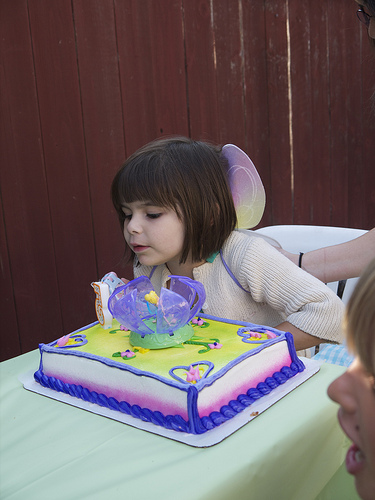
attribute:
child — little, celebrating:
[109, 133, 349, 356]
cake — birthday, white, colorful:
[31, 267, 308, 439]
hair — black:
[110, 142, 239, 265]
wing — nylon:
[106, 273, 156, 333]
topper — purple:
[106, 273, 207, 336]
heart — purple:
[167, 358, 216, 389]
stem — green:
[184, 336, 222, 357]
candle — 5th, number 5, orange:
[89, 269, 131, 329]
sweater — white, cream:
[126, 232, 346, 349]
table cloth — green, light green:
[1, 345, 353, 500]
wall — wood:
[1, 4, 375, 366]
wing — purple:
[216, 136, 270, 236]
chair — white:
[249, 221, 366, 359]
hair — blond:
[342, 258, 374, 378]